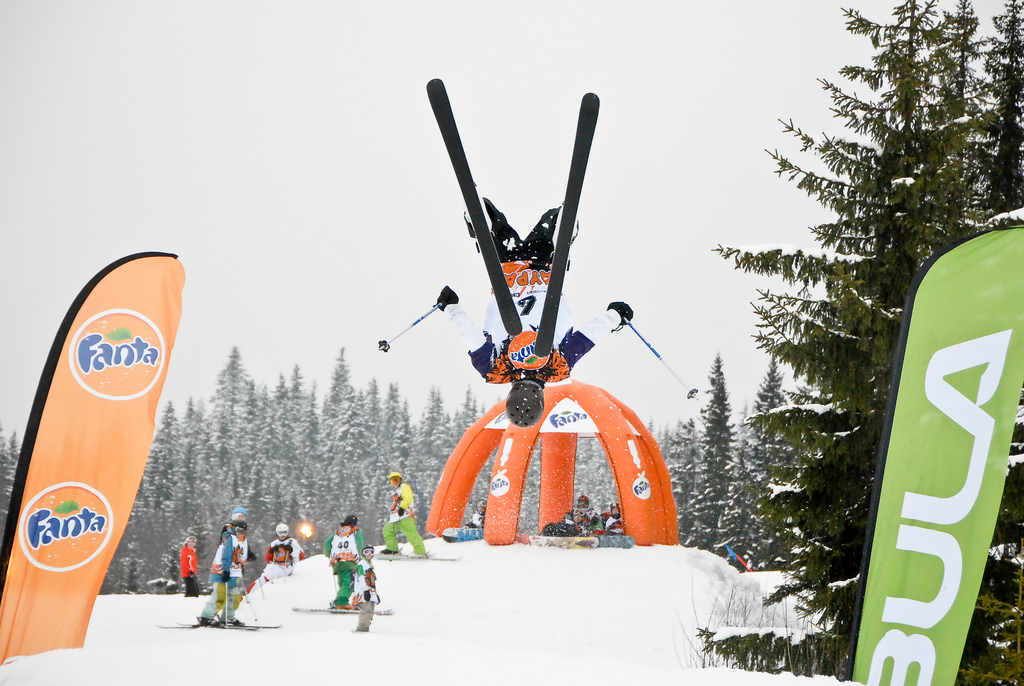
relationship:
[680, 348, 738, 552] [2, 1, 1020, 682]
tree in a woods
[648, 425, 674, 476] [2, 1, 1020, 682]
tree in woods